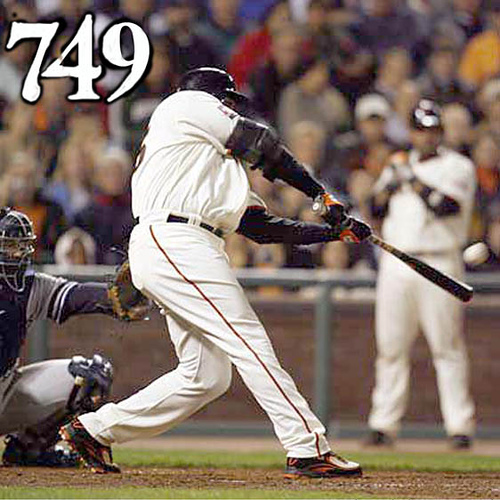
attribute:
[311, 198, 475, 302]
bat — black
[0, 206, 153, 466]
catcher — crouched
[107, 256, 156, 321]
mitt — brown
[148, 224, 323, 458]
stripe — red, thin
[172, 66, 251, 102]
helmet — black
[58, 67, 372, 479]
batter — swinging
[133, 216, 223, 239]
belt — black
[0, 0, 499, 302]
people — watching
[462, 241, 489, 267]
baseball — white, moving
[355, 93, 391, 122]
baseball cap — white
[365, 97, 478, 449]
baseball player — standing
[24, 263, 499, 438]
rail — grey